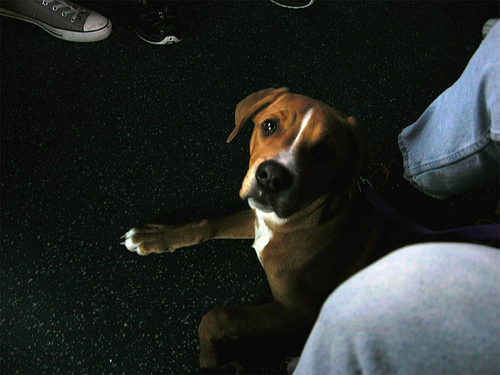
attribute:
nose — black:
[254, 158, 295, 196]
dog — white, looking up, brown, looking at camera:
[118, 83, 499, 374]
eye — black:
[259, 116, 280, 139]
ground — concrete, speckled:
[0, 0, 499, 374]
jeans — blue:
[289, 19, 497, 374]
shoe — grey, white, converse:
[0, 0, 114, 43]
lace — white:
[39, 0, 91, 24]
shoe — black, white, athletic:
[129, 0, 189, 47]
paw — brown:
[118, 220, 172, 256]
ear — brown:
[226, 85, 293, 145]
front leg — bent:
[196, 298, 306, 374]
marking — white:
[285, 103, 317, 155]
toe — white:
[120, 239, 139, 250]